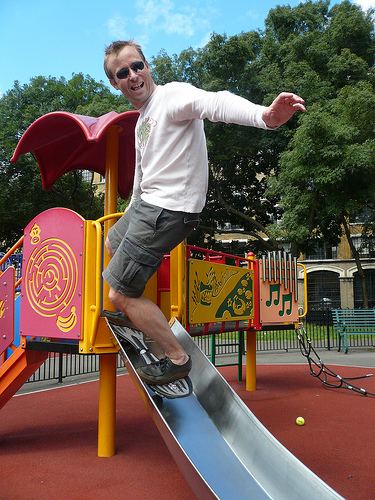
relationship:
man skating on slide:
[76, 34, 308, 395] [96, 300, 344, 497]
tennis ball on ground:
[286, 402, 311, 431] [223, 356, 373, 498]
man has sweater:
[76, 34, 308, 395] [102, 82, 268, 211]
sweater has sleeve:
[102, 82, 268, 211] [196, 84, 269, 140]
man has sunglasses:
[76, 34, 308, 395] [109, 57, 156, 78]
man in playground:
[76, 34, 308, 395] [11, 100, 370, 484]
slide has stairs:
[96, 300, 344, 497] [5, 338, 50, 409]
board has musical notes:
[254, 252, 314, 330] [262, 281, 299, 317]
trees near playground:
[229, 4, 369, 247] [11, 100, 370, 484]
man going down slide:
[76, 34, 308, 395] [96, 300, 344, 497]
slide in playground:
[96, 300, 344, 497] [11, 100, 370, 484]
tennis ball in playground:
[286, 402, 311, 431] [11, 100, 370, 484]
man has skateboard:
[76, 34, 308, 395] [109, 318, 200, 407]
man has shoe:
[76, 34, 308, 395] [137, 355, 199, 384]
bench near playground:
[328, 291, 369, 353] [11, 100, 370, 484]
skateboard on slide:
[109, 318, 200, 407] [96, 300, 344, 497]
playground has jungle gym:
[11, 100, 370, 484] [14, 194, 311, 437]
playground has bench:
[11, 100, 370, 484] [328, 291, 369, 353]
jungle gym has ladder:
[14, 194, 311, 437] [295, 317, 369, 401]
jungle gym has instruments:
[14, 194, 311, 437] [255, 243, 304, 290]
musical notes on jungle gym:
[262, 281, 299, 317] [14, 194, 311, 437]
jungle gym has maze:
[14, 194, 311, 437] [22, 218, 85, 340]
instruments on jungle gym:
[255, 243, 304, 290] [14, 194, 311, 437]